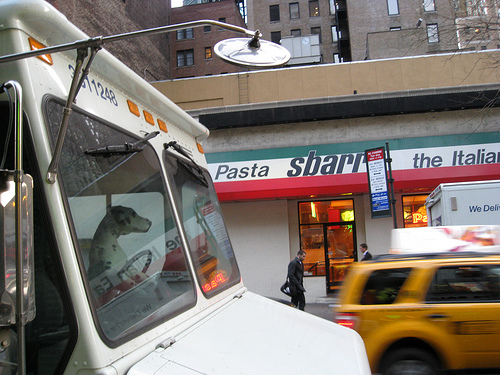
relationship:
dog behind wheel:
[76, 194, 161, 245] [114, 242, 188, 291]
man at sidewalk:
[277, 242, 312, 327] [305, 294, 365, 326]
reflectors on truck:
[125, 96, 167, 132] [5, 0, 375, 370]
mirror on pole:
[215, 29, 288, 69] [1, 17, 266, 64]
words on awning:
[215, 147, 498, 179] [210, 131, 497, 201]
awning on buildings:
[210, 131, 497, 201] [172, 4, 483, 58]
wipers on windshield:
[87, 130, 207, 178] [42, 92, 242, 343]